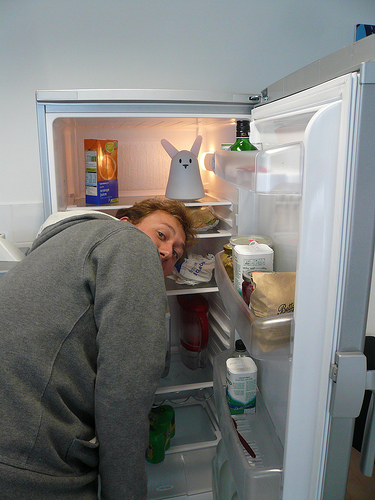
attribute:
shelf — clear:
[72, 186, 234, 245]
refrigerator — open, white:
[38, 93, 364, 500]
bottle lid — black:
[236, 119, 251, 137]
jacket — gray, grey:
[0, 215, 171, 500]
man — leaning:
[9, 197, 194, 500]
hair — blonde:
[133, 199, 193, 228]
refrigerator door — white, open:
[226, 77, 355, 493]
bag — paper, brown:
[253, 269, 290, 340]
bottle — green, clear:
[231, 115, 257, 156]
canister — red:
[185, 297, 211, 356]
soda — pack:
[143, 401, 178, 469]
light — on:
[197, 141, 220, 185]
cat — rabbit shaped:
[162, 131, 207, 204]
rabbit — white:
[158, 136, 207, 206]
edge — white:
[71, 203, 231, 301]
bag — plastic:
[167, 248, 222, 287]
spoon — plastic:
[173, 277, 200, 289]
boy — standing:
[11, 197, 191, 497]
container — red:
[235, 279, 253, 306]